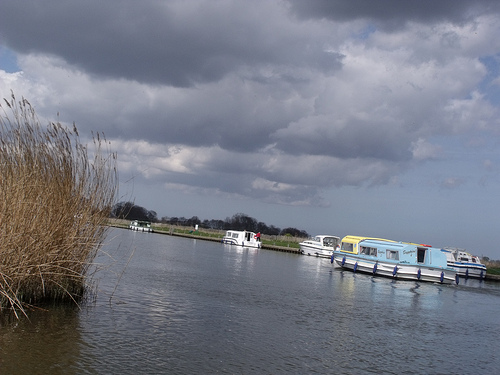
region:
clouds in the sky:
[144, 28, 349, 149]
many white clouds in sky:
[157, 51, 393, 213]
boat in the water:
[306, 218, 466, 315]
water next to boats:
[192, 243, 318, 340]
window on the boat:
[348, 234, 390, 265]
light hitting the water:
[119, 276, 213, 336]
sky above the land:
[360, 178, 473, 225]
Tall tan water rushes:
[0, 94, 117, 311]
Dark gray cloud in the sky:
[0, 0, 239, 87]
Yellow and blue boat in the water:
[335, 235, 457, 283]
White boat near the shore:
[225, 227, 267, 252]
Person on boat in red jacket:
[255, 232, 262, 241]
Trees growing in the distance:
[104, 203, 307, 235]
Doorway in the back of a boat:
[411, 245, 428, 260]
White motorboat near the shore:
[293, 231, 332, 258]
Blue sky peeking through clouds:
[479, 53, 499, 82]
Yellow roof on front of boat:
[337, 233, 371, 250]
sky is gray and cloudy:
[0, 0, 497, 259]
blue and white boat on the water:
[329, 239, 459, 282]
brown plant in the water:
[0, 88, 141, 323]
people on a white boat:
[223, 226, 262, 245]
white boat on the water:
[3, 220, 497, 370]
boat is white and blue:
[445, 248, 485, 276]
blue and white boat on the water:
[445, 250, 487, 279]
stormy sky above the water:
[0, 0, 497, 258]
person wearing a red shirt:
[254, 228, 263, 241]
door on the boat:
[415, 243, 429, 265]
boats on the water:
[130, 217, 482, 288]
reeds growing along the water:
[3, 90, 114, 311]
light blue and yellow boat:
[331, 234, 450, 280]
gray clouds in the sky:
[7, 4, 493, 205]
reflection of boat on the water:
[323, 264, 437, 308]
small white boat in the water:
[224, 229, 260, 244]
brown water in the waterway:
[34, 217, 498, 365]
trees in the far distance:
[110, 193, 310, 238]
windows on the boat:
[340, 244, 404, 260]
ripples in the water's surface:
[42, 234, 475, 370]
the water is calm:
[154, 242, 336, 342]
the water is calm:
[209, 279, 344, 344]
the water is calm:
[208, 249, 392, 364]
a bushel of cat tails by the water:
[2, 88, 152, 320]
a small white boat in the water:
[210, 223, 270, 263]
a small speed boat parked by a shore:
[117, 213, 157, 237]